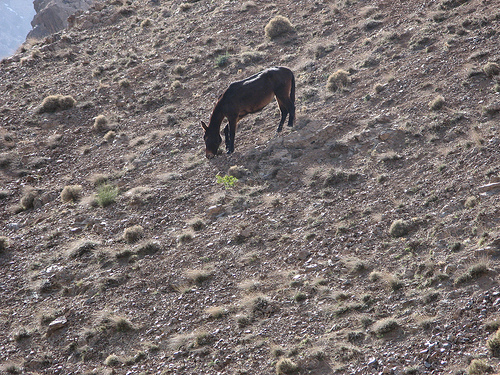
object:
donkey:
[197, 65, 298, 161]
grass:
[198, 268, 304, 328]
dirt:
[0, 0, 498, 374]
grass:
[364, 313, 399, 339]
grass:
[266, 328, 367, 374]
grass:
[482, 328, 499, 356]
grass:
[423, 249, 495, 299]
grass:
[359, 209, 416, 241]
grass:
[20, 307, 145, 374]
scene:
[0, 0, 498, 375]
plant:
[211, 172, 241, 191]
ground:
[0, 0, 499, 374]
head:
[196, 117, 223, 159]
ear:
[197, 121, 210, 131]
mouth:
[204, 151, 213, 160]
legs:
[220, 112, 238, 149]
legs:
[273, 89, 290, 128]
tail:
[275, 65, 299, 107]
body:
[212, 65, 297, 156]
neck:
[203, 106, 226, 130]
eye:
[200, 133, 212, 140]